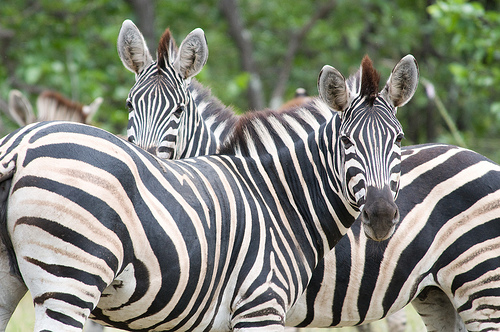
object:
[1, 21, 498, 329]
two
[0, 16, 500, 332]
zebras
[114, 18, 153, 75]
ears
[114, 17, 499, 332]
zebra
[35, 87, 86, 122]
mane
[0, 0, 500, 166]
blurred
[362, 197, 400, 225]
nose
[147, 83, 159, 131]
stripes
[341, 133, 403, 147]
pair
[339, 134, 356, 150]
eyes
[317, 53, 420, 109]
top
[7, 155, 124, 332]
hind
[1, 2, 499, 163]
background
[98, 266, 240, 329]
belly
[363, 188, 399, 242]
muzzle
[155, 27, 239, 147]
mane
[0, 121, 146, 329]
backside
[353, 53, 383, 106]
hair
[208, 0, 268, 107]
branch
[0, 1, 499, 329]
picture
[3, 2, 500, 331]
outdoors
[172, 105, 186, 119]
eyes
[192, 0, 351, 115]
tree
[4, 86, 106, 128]
head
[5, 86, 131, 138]
zebra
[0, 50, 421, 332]
zebra